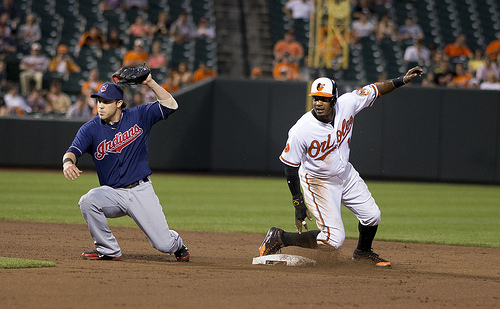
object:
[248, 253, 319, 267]
base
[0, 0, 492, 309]
baseball game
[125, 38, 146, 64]
person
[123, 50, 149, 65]
shirt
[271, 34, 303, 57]
person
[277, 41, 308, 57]
shirt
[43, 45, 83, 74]
person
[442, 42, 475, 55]
shirt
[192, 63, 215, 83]
person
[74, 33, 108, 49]
shirt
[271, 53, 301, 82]
person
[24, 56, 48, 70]
shirt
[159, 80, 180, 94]
shirt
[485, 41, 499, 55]
shirt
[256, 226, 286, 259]
shoe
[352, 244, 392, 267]
shoe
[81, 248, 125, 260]
shoe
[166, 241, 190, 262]
shoe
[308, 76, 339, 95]
hat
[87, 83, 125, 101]
hat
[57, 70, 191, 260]
person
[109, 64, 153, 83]
baseball glove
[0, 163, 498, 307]
field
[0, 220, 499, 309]
mound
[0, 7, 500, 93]
stand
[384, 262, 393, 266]
tip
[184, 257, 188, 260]
tip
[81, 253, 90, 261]
tip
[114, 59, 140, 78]
marking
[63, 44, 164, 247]
man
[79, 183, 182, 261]
pants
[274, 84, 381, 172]
shirt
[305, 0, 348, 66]
tower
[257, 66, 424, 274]
person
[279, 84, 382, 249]
uniform